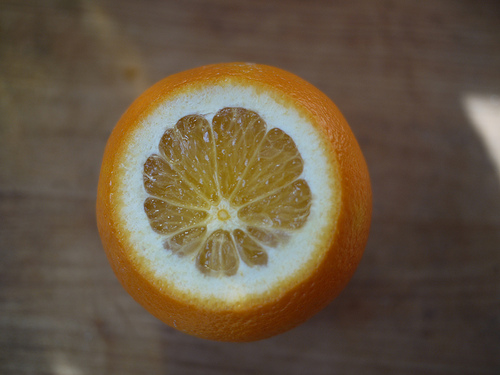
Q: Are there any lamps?
A: No, there are no lamps.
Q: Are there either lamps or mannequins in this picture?
A: No, there are no lamps or mannequins.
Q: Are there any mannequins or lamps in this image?
A: No, there are no lamps or mannequins.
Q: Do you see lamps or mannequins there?
A: No, there are no lamps or mannequins.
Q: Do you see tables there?
A: Yes, there is a table.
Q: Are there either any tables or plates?
A: Yes, there is a table.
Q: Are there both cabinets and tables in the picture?
A: No, there is a table but no cabinets.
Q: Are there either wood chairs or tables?
A: Yes, there is a wood table.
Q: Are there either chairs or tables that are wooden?
A: Yes, the table is wooden.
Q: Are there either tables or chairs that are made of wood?
A: Yes, the table is made of wood.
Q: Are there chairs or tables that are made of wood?
A: Yes, the table is made of wood.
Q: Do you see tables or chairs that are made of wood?
A: Yes, the table is made of wood.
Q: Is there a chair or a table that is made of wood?
A: Yes, the table is made of wood.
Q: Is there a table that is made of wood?
A: Yes, there is a table that is made of wood.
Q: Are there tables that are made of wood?
A: Yes, there is a table that is made of wood.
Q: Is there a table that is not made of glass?
A: Yes, there is a table that is made of wood.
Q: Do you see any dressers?
A: No, there are no dressers.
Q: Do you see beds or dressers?
A: No, there are no dressers or beds.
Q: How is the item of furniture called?
A: The piece of furniture is a table.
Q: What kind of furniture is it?
A: The piece of furniture is a table.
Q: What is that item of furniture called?
A: This is a table.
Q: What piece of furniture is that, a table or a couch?
A: This is a table.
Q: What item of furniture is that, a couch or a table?
A: This is a table.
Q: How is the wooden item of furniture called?
A: The piece of furniture is a table.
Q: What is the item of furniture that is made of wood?
A: The piece of furniture is a table.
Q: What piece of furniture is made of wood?
A: The piece of furniture is a table.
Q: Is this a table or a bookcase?
A: This is a table.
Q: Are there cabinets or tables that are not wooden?
A: No, there is a table but it is wooden.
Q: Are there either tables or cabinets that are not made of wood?
A: No, there is a table but it is made of wood.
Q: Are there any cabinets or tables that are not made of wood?
A: No, there is a table but it is made of wood.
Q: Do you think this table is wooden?
A: Yes, the table is wooden.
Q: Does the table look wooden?
A: Yes, the table is wooden.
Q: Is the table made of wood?
A: Yes, the table is made of wood.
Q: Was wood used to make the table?
A: Yes, the table is made of wood.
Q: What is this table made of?
A: The table is made of wood.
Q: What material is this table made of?
A: The table is made of wood.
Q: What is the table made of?
A: The table is made of wood.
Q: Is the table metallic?
A: No, the table is wooden.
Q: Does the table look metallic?
A: No, the table is wooden.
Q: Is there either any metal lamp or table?
A: No, there is a table but it is wooden.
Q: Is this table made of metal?
A: No, the table is made of wood.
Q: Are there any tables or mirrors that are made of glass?
A: No, there is a table but it is made of wood.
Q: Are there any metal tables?
A: No, there is a table but it is made of wood.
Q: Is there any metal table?
A: No, there is a table but it is made of wood.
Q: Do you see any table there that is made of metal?
A: No, there is a table but it is made of wood.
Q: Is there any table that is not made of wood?
A: No, there is a table but it is made of wood.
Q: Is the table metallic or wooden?
A: The table is wooden.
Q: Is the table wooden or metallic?
A: The table is wooden.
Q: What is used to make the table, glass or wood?
A: The table is made of wood.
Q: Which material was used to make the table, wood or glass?
A: The table is made of wood.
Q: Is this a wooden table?
A: Yes, this is a wooden table.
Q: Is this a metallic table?
A: No, this is a wooden table.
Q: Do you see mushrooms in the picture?
A: No, there are no mushrooms.